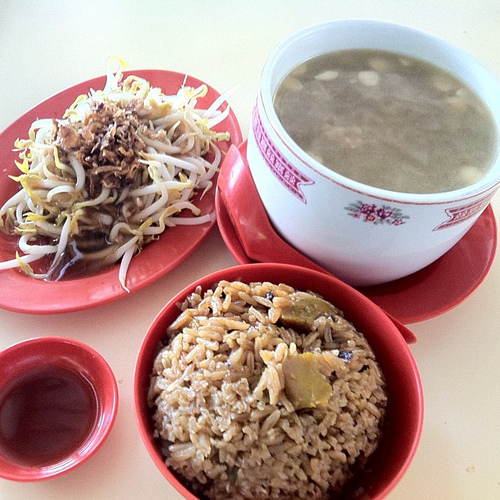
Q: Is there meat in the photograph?
A: Yes, there is meat.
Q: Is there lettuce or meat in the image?
A: Yes, there is meat.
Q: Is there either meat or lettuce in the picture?
A: Yes, there is meat.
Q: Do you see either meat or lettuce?
A: Yes, there is meat.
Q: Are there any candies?
A: No, there are no candies.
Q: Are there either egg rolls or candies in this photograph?
A: No, there are no candies or egg rolls.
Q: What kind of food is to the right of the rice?
A: The food is meat.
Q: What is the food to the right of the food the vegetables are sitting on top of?
A: The food is meat.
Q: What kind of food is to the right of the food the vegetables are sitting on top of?
A: The food is meat.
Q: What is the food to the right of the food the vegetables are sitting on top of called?
A: The food is meat.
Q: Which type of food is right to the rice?
A: The food is meat.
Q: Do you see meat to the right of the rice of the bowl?
A: Yes, there is meat to the right of the rice.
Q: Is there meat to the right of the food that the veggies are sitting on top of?
A: Yes, there is meat to the right of the rice.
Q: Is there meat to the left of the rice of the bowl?
A: No, the meat is to the right of the rice.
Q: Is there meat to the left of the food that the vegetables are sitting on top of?
A: No, the meat is to the right of the rice.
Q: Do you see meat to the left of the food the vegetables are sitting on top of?
A: No, the meat is to the right of the rice.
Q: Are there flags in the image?
A: No, there are no flags.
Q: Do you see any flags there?
A: No, there are no flags.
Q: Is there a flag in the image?
A: No, there are no flags.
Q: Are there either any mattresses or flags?
A: No, there are no flags or mattresses.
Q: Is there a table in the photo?
A: Yes, there is a table.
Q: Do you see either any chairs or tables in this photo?
A: Yes, there is a table.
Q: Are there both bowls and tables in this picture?
A: Yes, there are both a table and a bowl.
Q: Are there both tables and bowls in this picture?
A: Yes, there are both a table and a bowl.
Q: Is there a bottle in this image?
A: No, there are no bottles.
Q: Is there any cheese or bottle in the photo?
A: No, there are no bottles or cheese.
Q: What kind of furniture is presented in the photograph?
A: The furniture is a table.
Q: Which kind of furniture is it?
A: The piece of furniture is a table.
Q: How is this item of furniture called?
A: That is a table.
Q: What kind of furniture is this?
A: That is a table.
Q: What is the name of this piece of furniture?
A: That is a table.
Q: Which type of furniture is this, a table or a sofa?
A: That is a table.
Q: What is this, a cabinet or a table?
A: This is a table.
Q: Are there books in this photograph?
A: No, there are no books.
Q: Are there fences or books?
A: No, there are no books or fences.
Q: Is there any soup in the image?
A: Yes, there is soup.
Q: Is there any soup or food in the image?
A: Yes, there is soup.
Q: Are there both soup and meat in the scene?
A: Yes, there are both soup and meat.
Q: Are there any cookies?
A: No, there are no cookies.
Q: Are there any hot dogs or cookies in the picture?
A: No, there are no cookies or hot dogs.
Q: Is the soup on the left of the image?
A: No, the soup is on the right of the image.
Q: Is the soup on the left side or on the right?
A: The soup is on the right of the image.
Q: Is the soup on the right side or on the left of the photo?
A: The soup is on the right of the image.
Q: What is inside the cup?
A: The soup is inside the cup.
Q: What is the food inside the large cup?
A: The food is soup.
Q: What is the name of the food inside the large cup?
A: The food is soup.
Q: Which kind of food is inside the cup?
A: The food is soup.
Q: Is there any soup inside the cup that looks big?
A: Yes, there is soup inside the cup.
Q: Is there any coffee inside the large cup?
A: No, there is soup inside the cup.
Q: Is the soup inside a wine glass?
A: No, the soup is inside the cup.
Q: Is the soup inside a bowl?
A: Yes, the soup is inside a bowl.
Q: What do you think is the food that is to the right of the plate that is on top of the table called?
A: The food is soup.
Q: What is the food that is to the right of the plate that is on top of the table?
A: The food is soup.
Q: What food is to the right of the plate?
A: The food is soup.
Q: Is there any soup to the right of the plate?
A: Yes, there is soup to the right of the plate.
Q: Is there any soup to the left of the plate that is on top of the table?
A: No, the soup is to the right of the plate.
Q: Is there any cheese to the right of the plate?
A: No, there is soup to the right of the plate.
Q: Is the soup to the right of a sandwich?
A: No, the soup is to the right of a plate.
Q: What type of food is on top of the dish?
A: The food is soup.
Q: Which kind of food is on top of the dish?
A: The food is soup.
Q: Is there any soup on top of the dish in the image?
A: Yes, there is soup on top of the dish.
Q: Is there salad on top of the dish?
A: No, there is soup on top of the dish.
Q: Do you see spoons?
A: Yes, there is a spoon.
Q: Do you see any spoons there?
A: Yes, there is a spoon.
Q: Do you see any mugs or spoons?
A: Yes, there is a spoon.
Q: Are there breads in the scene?
A: No, there are no breads.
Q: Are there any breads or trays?
A: No, there are no breads or trays.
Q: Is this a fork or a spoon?
A: This is a spoon.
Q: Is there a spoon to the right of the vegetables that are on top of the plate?
A: Yes, there is a spoon to the right of the vegetables.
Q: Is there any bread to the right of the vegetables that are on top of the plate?
A: No, there is a spoon to the right of the veggies.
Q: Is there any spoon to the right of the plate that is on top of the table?
A: Yes, there is a spoon to the right of the plate.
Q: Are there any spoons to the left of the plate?
A: No, the spoon is to the right of the plate.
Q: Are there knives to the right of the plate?
A: No, there is a spoon to the right of the plate.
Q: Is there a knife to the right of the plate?
A: No, there is a spoon to the right of the plate.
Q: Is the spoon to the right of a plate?
A: Yes, the spoon is to the right of a plate.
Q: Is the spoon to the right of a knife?
A: No, the spoon is to the right of a plate.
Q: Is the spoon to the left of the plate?
A: No, the spoon is to the right of the plate.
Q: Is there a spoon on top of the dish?
A: Yes, there is a spoon on top of the dish.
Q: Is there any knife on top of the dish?
A: No, there is a spoon on top of the dish.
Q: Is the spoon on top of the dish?
A: Yes, the spoon is on top of the dish.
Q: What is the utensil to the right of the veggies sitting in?
A: The spoon is sitting in the bowl.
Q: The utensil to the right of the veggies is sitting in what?
A: The spoon is sitting in the bowl.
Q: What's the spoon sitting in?
A: The spoon is sitting in the bowl.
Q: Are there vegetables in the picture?
A: Yes, there are vegetables.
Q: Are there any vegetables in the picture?
A: Yes, there are vegetables.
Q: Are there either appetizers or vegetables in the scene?
A: Yes, there are vegetables.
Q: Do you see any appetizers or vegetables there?
A: Yes, there are vegetables.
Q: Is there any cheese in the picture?
A: No, there is no cheese.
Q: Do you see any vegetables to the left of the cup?
A: Yes, there are vegetables to the left of the cup.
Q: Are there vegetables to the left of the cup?
A: Yes, there are vegetables to the left of the cup.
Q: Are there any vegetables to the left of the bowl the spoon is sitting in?
A: Yes, there are vegetables to the left of the bowl.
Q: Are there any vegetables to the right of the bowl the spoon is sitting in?
A: No, the vegetables are to the left of the bowl.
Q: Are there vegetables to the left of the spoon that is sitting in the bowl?
A: Yes, there are vegetables to the left of the spoon.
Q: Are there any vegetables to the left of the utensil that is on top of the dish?
A: Yes, there are vegetables to the left of the spoon.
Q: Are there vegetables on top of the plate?
A: Yes, there are vegetables on top of the plate.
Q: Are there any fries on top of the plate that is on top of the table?
A: No, there are vegetables on top of the plate.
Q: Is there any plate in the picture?
A: Yes, there is a plate.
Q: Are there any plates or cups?
A: Yes, there is a plate.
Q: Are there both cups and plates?
A: Yes, there are both a plate and a cup.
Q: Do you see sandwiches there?
A: No, there are no sandwiches.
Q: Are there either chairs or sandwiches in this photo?
A: No, there are no sandwiches or chairs.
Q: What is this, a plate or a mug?
A: This is a plate.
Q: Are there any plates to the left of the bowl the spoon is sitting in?
A: Yes, there is a plate to the left of the bowl.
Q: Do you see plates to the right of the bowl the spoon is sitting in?
A: No, the plate is to the left of the bowl.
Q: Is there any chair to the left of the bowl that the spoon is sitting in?
A: No, there is a plate to the left of the bowl.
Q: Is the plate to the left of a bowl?
A: Yes, the plate is to the left of a bowl.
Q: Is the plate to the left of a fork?
A: No, the plate is to the left of a bowl.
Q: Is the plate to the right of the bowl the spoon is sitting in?
A: No, the plate is to the left of the bowl.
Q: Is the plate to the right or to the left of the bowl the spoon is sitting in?
A: The plate is to the left of the bowl.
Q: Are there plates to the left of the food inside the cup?
A: Yes, there is a plate to the left of the soup.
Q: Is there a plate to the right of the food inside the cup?
A: No, the plate is to the left of the soup.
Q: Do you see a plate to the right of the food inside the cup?
A: No, the plate is to the left of the soup.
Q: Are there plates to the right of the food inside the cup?
A: No, the plate is to the left of the soup.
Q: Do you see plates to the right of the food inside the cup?
A: No, the plate is to the left of the soup.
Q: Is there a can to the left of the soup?
A: No, there is a plate to the left of the soup.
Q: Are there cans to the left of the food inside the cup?
A: No, there is a plate to the left of the soup.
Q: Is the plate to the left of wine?
A: No, the plate is to the left of the soup.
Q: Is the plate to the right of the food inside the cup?
A: No, the plate is to the left of the soup.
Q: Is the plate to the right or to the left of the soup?
A: The plate is to the left of the soup.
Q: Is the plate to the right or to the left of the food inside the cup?
A: The plate is to the left of the soup.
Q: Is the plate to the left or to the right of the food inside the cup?
A: The plate is to the left of the soup.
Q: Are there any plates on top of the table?
A: Yes, there is a plate on top of the table.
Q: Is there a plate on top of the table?
A: Yes, there is a plate on top of the table.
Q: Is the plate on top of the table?
A: Yes, the plate is on top of the table.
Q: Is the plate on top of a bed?
A: No, the plate is on top of the table.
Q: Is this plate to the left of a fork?
A: No, the plate is to the left of the bowl.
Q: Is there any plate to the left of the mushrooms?
A: Yes, there is a plate to the left of the mushrooms.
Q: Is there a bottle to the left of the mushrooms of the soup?
A: No, there is a plate to the left of the mushrooms.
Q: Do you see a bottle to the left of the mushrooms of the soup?
A: No, there is a plate to the left of the mushrooms.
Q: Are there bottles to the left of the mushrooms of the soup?
A: No, there is a plate to the left of the mushrooms.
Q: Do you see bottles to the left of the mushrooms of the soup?
A: No, there is a plate to the left of the mushrooms.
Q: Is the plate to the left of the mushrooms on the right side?
A: Yes, the plate is to the left of the mushrooms.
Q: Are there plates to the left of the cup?
A: Yes, there is a plate to the left of the cup.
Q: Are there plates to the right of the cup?
A: No, the plate is to the left of the cup.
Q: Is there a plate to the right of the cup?
A: No, the plate is to the left of the cup.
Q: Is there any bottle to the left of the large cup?
A: No, there is a plate to the left of the cup.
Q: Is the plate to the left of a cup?
A: Yes, the plate is to the left of a cup.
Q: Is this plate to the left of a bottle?
A: No, the plate is to the left of a cup.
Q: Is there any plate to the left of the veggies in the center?
A: Yes, there is a plate to the left of the veggies.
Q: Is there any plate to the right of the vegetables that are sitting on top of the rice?
A: No, the plate is to the left of the veggies.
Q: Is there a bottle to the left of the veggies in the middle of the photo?
A: No, there is a plate to the left of the veggies.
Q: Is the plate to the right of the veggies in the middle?
A: No, the plate is to the left of the veggies.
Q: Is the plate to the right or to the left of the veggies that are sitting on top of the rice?
A: The plate is to the left of the veggies.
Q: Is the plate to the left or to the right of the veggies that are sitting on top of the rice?
A: The plate is to the left of the veggies.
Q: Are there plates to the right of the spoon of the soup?
A: No, the plate is to the left of the spoon.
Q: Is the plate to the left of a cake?
A: No, the plate is to the left of the spoon.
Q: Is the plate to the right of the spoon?
A: No, the plate is to the left of the spoon.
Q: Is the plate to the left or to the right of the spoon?
A: The plate is to the left of the spoon.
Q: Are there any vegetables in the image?
A: Yes, there are vegetables.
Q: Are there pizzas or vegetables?
A: Yes, there are vegetables.